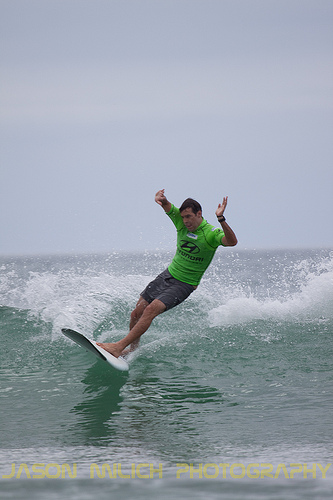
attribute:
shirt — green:
[166, 203, 224, 285]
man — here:
[96, 189, 238, 357]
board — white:
[60, 326, 130, 372]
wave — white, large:
[1, 253, 332, 346]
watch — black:
[218, 216, 227, 224]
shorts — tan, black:
[139, 269, 196, 309]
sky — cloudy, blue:
[0, 0, 332, 255]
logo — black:
[177, 236, 205, 263]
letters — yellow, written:
[7, 461, 332, 484]